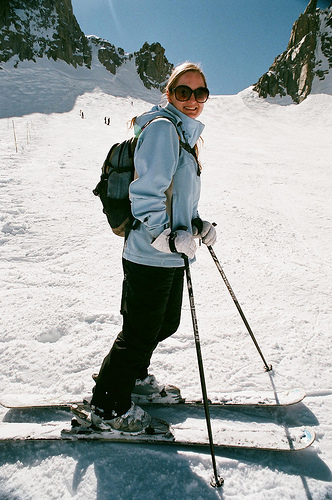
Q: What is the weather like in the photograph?
A: It is clear.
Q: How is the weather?
A: It is clear.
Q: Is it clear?
A: Yes, it is clear.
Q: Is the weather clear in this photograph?
A: Yes, it is clear.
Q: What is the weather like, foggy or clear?
A: It is clear.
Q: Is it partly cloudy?
A: No, it is clear.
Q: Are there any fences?
A: No, there are no fences.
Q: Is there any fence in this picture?
A: No, there are no fences.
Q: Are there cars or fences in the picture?
A: No, there are no fences or cars.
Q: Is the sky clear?
A: Yes, the sky is clear.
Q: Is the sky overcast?
A: No, the sky is clear.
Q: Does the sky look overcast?
A: No, the sky is clear.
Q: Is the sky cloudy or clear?
A: The sky is clear.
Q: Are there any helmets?
A: No, there are no helmets.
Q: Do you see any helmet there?
A: No, there are no helmets.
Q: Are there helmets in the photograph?
A: No, there are no helmets.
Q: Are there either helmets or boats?
A: No, there are no helmets or boats.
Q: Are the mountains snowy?
A: Yes, the mountains are snowy.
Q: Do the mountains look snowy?
A: Yes, the mountains are snowy.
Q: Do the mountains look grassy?
A: No, the mountains are snowy.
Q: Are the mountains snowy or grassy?
A: The mountains are snowy.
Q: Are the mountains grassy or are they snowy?
A: The mountains are snowy.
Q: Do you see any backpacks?
A: Yes, there is a backpack.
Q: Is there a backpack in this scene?
A: Yes, there is a backpack.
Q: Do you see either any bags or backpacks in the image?
A: Yes, there is a backpack.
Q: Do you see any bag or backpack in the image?
A: Yes, there is a backpack.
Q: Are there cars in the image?
A: No, there are no cars.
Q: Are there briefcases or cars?
A: No, there are no cars or briefcases.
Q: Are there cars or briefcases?
A: No, there are no cars or briefcases.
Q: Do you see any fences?
A: No, there are no fences.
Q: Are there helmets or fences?
A: No, there are no fences or helmets.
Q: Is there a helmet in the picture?
A: No, there are no helmets.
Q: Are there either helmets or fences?
A: No, there are no helmets or fences.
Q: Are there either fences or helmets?
A: No, there are no helmets or fences.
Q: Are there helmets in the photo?
A: No, there are no helmets.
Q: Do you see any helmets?
A: No, there are no helmets.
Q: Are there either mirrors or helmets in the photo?
A: No, there are no helmets or mirrors.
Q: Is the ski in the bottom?
A: Yes, the ski is in the bottom of the image.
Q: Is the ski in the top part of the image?
A: No, the ski is in the bottom of the image.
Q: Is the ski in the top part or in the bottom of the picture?
A: The ski is in the bottom of the image.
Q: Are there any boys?
A: No, there are no boys.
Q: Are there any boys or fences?
A: No, there are no boys or fences.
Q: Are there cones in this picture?
A: No, there are no cones.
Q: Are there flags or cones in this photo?
A: No, there are no cones or flags.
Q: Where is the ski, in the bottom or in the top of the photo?
A: The ski is in the bottom of the image.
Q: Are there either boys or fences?
A: No, there are no boys or fences.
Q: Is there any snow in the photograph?
A: Yes, there is snow.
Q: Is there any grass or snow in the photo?
A: Yes, there is snow.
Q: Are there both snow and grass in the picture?
A: No, there is snow but no grass.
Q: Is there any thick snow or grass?
A: Yes, there is thick snow.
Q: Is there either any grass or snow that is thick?
A: Yes, the snow is thick.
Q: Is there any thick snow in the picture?
A: Yes, there is thick snow.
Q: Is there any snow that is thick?
A: Yes, there is snow that is thick.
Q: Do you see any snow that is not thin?
A: Yes, there is thick snow.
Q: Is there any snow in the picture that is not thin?
A: Yes, there is thick snow.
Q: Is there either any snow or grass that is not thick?
A: No, there is snow but it is thick.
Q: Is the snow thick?
A: Yes, the snow is thick.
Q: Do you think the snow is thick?
A: Yes, the snow is thick.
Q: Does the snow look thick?
A: Yes, the snow is thick.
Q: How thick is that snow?
A: The snow is thick.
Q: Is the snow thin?
A: No, the snow is thick.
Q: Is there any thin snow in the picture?
A: No, there is snow but it is thick.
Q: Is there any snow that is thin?
A: No, there is snow but it is thick.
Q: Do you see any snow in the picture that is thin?
A: No, there is snow but it is thick.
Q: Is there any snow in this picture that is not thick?
A: No, there is snow but it is thick.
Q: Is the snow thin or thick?
A: The snow is thick.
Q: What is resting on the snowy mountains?
A: The snow is resting on the mountains.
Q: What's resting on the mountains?
A: The snow is resting on the mountains.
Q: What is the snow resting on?
A: The snow is resting on the mountains.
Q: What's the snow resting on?
A: The snow is resting on the mountains.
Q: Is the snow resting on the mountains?
A: Yes, the snow is resting on the mountains.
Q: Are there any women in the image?
A: Yes, there is a woman.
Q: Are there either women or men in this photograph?
A: Yes, there is a woman.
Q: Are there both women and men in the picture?
A: No, there is a woman but no men.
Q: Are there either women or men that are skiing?
A: Yes, the woman is skiing.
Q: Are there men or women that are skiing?
A: Yes, the woman is skiing.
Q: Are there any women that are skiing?
A: Yes, there is a woman that is skiing.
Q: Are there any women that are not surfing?
A: Yes, there is a woman that is skiing.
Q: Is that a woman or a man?
A: That is a woman.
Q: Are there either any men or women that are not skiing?
A: No, there is a woman but she is skiing.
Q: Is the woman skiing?
A: Yes, the woman is skiing.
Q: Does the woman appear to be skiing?
A: Yes, the woman is skiing.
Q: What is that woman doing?
A: The woman is skiing.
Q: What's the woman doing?
A: The woman is skiing.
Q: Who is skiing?
A: The woman is skiing.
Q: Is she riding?
A: No, the woman is skiing.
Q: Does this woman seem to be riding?
A: No, the woman is skiing.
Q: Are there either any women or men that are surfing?
A: No, there is a woman but she is skiing.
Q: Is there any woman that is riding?
A: No, there is a woman but she is skiing.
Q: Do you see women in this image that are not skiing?
A: No, there is a woman but she is skiing.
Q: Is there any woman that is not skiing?
A: No, there is a woman but she is skiing.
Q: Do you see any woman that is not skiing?
A: No, there is a woman but she is skiing.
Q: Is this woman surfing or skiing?
A: The woman is skiing.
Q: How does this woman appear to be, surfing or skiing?
A: The woman is skiing.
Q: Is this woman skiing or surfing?
A: The woman is skiing.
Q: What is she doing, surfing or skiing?
A: The woman is skiing.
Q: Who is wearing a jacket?
A: The woman is wearing a jacket.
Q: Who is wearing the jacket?
A: The woman is wearing a jacket.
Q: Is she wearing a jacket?
A: Yes, the woman is wearing a jacket.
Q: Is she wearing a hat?
A: No, the woman is wearing a jacket.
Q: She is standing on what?
A: The woman is standing on the ski.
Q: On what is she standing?
A: The woman is standing on the ski.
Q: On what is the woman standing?
A: The woman is standing on the ski.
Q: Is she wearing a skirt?
A: No, the woman is wearing a glove.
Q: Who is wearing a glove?
A: The woman is wearing a glove.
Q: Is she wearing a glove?
A: Yes, the woman is wearing a glove.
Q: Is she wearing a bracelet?
A: No, the woman is wearing a glove.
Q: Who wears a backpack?
A: The woman wears a backpack.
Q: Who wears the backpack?
A: The woman wears a backpack.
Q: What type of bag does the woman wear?
A: The woman wears a backpack.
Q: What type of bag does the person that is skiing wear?
A: The woman wears a backpack.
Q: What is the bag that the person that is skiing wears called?
A: The bag is a backpack.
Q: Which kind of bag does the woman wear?
A: The woman wears a backpack.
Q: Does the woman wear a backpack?
A: Yes, the woman wears a backpack.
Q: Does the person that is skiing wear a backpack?
A: Yes, the woman wears a backpack.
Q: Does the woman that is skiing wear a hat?
A: No, the woman wears a backpack.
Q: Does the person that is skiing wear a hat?
A: No, the woman wears a backpack.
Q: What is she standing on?
A: The woman is standing on the ski.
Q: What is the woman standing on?
A: The woman is standing on the ski.